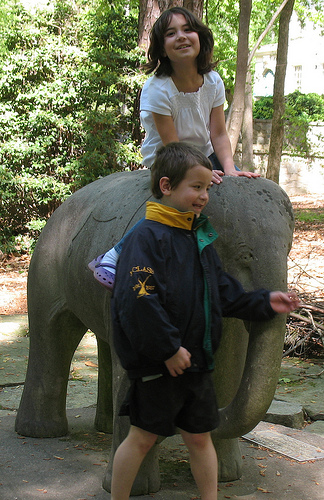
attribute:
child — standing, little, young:
[115, 144, 301, 493]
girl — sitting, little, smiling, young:
[87, 9, 260, 288]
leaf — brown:
[52, 453, 64, 461]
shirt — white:
[139, 71, 226, 169]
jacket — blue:
[110, 200, 272, 375]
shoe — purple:
[87, 252, 116, 290]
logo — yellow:
[128, 265, 155, 299]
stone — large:
[267, 399, 306, 428]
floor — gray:
[2, 301, 323, 500]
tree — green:
[0, 1, 89, 261]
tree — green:
[75, 1, 138, 191]